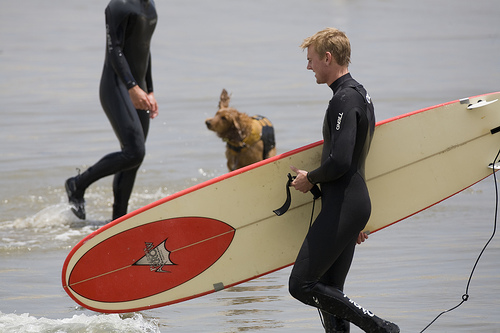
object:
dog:
[203, 90, 275, 171]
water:
[0, 1, 498, 332]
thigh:
[291, 211, 360, 282]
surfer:
[289, 25, 401, 333]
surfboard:
[63, 91, 500, 313]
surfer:
[64, 1, 158, 221]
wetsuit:
[288, 72, 399, 332]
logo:
[131, 237, 178, 274]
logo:
[336, 112, 345, 130]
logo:
[105, 24, 113, 52]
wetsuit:
[74, 0, 157, 220]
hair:
[299, 27, 353, 67]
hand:
[355, 231, 368, 244]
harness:
[227, 113, 276, 159]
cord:
[307, 150, 500, 332]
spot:
[69, 216, 235, 303]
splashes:
[0, 308, 158, 332]